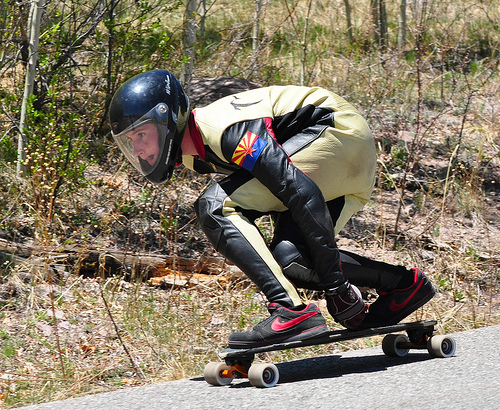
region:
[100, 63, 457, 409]
a skate broader on a road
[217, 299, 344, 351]
red and black shoe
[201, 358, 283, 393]
white wheels on skate broad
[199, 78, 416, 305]
cream and black leather suit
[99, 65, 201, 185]
black ans silver helmet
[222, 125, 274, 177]
blue and red , yellow pitch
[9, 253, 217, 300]
a rotten log in the woods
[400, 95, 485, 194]
rocks on a bank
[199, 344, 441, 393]
shadow under skate broad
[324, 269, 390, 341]
red and gray glove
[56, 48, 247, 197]
woman wearing a helmet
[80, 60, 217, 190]
woman's helmet is black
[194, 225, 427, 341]
woman's shoes are black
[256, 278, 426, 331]
red logo on woman's shoes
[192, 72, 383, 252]
woman's clothes are yellow and black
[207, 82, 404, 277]
woman's clothes made of leather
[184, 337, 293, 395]
skateboard wheels are white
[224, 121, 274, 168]
blue yellow and red logo on sleeve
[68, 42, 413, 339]
woman is kneeling down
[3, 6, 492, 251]
trees behind the woman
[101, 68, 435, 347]
a person riding a skateboard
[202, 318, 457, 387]
a skateboard under the person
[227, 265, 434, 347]
red and black shoes on the person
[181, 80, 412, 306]
gold and black suit on the person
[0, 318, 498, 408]
a paved slope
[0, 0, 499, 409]
dry foliage behind the person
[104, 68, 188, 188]
black helmet on the person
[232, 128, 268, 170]
a colorful flag on the suit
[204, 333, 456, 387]
white wheels of the skateboard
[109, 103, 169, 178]
protective shield on the helmet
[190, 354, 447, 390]
Shadows of the man and the skateboard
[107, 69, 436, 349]
Man skateboarding on the road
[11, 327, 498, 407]
Concrete paved road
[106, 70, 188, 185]
Helmet on the man's head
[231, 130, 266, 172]
Flag on the man's arm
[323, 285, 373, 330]
Glove on the man's hand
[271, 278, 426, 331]
Nike logos on the man's shoes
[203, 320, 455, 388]
Skateboard under the man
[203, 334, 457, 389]
Wheels on the skateboard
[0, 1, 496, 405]
Trees and grasses on the hill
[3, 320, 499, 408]
The ground is asphalt.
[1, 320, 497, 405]
The asphalt is gray.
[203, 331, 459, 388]
The wheels are white.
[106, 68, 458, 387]
The person is on a skateboard.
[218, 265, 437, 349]
The person is wearing black shoes.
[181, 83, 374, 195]
The person is wearing a yellow top.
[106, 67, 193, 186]
The person is wearing a helmet.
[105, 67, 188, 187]
The helmet is black.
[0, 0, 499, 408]
Grass is in the background.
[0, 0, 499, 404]
The grass is green.